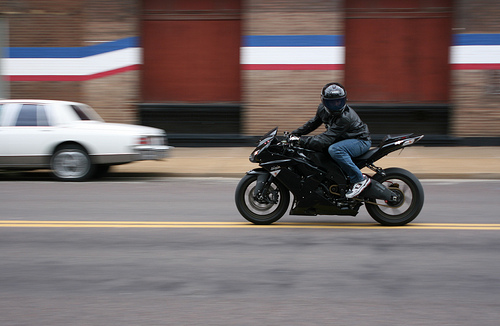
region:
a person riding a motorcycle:
[228, 77, 433, 230]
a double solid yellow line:
[3, 215, 498, 237]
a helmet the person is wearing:
[318, 80, 350, 119]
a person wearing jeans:
[285, 78, 375, 201]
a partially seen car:
[2, 95, 176, 183]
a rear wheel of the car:
[45, 145, 95, 182]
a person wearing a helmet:
[280, 79, 376, 201]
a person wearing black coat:
[286, 78, 376, 200]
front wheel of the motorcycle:
[230, 166, 292, 226]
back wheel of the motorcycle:
[361, 162, 426, 227]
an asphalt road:
[0, 174, 495, 316]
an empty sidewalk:
[105, 140, 499, 180]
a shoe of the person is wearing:
[341, 171, 372, 199]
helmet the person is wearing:
[319, 79, 351, 119]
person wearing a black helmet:
[318, 80, 351, 117]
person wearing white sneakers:
[336, 171, 375, 205]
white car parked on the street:
[3, 95, 175, 179]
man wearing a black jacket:
[295, 95, 370, 145]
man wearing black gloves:
[283, 130, 306, 152]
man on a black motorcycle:
[228, 71, 435, 231]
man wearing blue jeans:
[323, 133, 371, 178]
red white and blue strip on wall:
[227, 24, 348, 76]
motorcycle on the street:
[221, 103, 441, 245]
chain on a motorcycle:
[359, 175, 407, 215]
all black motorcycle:
[233, 82, 430, 219]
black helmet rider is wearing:
[320, 85, 342, 107]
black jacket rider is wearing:
[298, 109, 368, 145]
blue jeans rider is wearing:
[327, 137, 368, 179]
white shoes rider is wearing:
[345, 177, 370, 197]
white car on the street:
[0, 100, 173, 185]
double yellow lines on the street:
[0, 209, 498, 234]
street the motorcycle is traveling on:
[4, 172, 498, 324]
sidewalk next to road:
[135, 135, 499, 180]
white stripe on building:
[240, 45, 346, 62]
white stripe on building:
[448, 45, 498, 61]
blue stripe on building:
[7, 37, 142, 57]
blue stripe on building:
[238, 33, 342, 46]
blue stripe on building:
[451, 31, 499, 43]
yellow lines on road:
[1, 219, 498, 231]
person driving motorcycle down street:
[228, 78, 433, 229]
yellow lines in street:
[0, 214, 496, 239]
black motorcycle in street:
[229, 116, 436, 236]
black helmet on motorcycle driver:
[313, 79, 350, 116]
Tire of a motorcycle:
[233, 168, 291, 227]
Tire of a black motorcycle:
[228, 165, 293, 230]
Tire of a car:
[50, 144, 92, 182]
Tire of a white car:
[48, 143, 92, 185]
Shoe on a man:
[348, 175, 371, 198]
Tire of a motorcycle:
[365, 164, 426, 229]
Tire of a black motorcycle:
[362, 166, 424, 230]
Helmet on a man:
[317, 78, 349, 117]